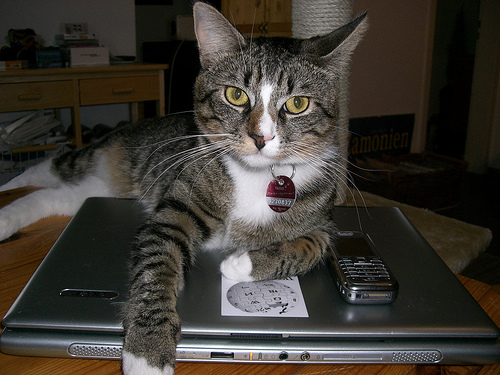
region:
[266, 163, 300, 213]
the cat has a red and silver tag around its collar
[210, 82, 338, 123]
the eyes of the cat are the color yellow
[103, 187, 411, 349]
the laptop is silver on the desk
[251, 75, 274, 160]
the nose on the cat is brown and white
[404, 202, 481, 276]
the rug on the floor is a beige color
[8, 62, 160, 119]
the desk is the color light brown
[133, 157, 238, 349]
the colors on the cat are white, black, and brown shades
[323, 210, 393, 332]
their is a phone on top of laptop on desk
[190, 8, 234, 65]
the color of the cat's ear is white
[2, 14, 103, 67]
their are items on the desk in the background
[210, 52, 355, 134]
Cat has yellow eyes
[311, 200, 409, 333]
A cell phone by cat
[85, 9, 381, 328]
Cat is black and white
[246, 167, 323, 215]
Red tag on collar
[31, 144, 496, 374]
Silver is the color of the laptop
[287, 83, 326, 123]
Cat's eyes are yellow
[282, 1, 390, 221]
Scratching post behind the cat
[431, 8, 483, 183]
This door is closed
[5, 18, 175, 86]
Stuff is on the counter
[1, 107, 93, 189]
Papers are underneath the counter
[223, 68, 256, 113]
A cats right eye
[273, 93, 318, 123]
A cats left eye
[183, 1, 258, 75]
A cats right ear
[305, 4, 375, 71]
A cats left ear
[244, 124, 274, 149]
A cats front nose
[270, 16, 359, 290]
Left side of cat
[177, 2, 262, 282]
Right side of cat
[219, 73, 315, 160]
A grey and whites cat face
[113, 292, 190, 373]
A cats front paw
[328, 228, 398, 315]
A old style cell phone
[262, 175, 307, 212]
IMMUNIZATION TAG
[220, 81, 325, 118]
CAT HAS YELLOW EYES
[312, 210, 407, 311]
OLD CELLULAR PHONE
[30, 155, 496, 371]
LAP TOP COMPUTER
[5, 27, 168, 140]
WOODEN DESK AGAINST THE WALL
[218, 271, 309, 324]
WIKI PEDIA LOGO ON THE PC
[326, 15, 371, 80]
HAS HAIR IN IT'S EARS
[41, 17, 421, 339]
THE CAT IS LAYING DOWN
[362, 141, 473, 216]
BASKET ON THE FLOOR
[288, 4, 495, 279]
CAT SCRATCH POST IN BACKGROUND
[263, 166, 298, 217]
A tag on the collar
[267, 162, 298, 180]
A silver hoop ring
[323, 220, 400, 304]
A cell phone on the lap top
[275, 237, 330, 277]
Stripes on the arm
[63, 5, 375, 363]
A cat on a lap top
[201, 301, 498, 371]
A laptop computer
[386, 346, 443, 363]
speaker on the back of the laptop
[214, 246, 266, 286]
The paw of a cat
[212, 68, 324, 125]
the cats green eyes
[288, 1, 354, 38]
A cat scratching post